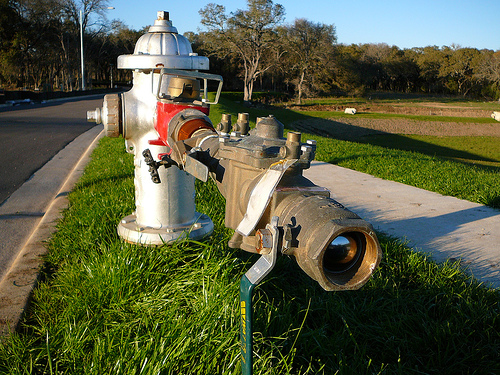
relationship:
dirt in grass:
[366, 125, 433, 131] [370, 156, 423, 177]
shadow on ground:
[344, 118, 378, 158] [465, 135, 484, 144]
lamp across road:
[66, 1, 90, 86] [53, 106, 75, 116]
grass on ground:
[370, 156, 423, 177] [465, 135, 484, 144]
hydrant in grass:
[117, 40, 197, 75] [370, 156, 423, 177]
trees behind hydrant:
[247, 42, 330, 96] [117, 40, 197, 75]